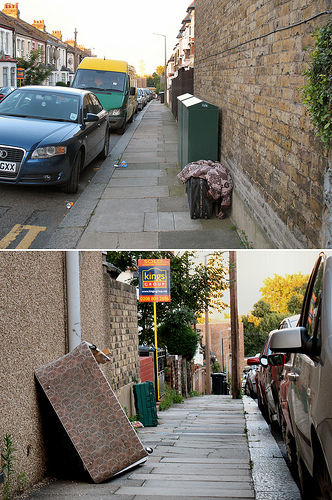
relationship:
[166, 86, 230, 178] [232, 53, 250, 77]
bins on ground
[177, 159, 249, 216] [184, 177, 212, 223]
clothing on suitcase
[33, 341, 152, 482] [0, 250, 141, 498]
furniture on wall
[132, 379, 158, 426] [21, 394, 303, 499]
bin on sidewalk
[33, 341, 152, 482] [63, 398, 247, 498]
furniture on sidewalk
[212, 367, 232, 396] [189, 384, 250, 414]
garbagebins on sidewalk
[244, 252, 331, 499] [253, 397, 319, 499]
cars along road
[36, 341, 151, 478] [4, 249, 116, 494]
piece on wall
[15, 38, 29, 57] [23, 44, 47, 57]
window on building